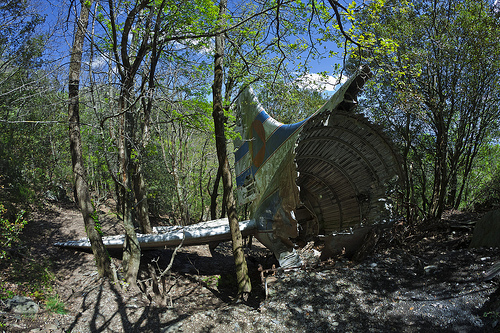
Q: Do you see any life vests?
A: No, there are no life vests.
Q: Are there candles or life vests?
A: No, there are no life vests or candles.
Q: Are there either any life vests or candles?
A: No, there are no life vests or candles.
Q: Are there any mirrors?
A: No, there are no mirrors.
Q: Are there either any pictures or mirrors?
A: No, there are no mirrors or pictures.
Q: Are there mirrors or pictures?
A: No, there are no mirrors or pictures.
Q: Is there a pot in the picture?
A: No, there are no pots.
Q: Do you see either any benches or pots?
A: No, there are no pots or benches.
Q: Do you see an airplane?
A: Yes, there is an airplane.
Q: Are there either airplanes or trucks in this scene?
A: Yes, there is an airplane.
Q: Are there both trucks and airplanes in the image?
A: No, there is an airplane but no trucks.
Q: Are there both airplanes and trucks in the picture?
A: No, there is an airplane but no trucks.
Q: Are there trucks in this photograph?
A: No, there are no trucks.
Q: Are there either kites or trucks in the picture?
A: No, there are no trucks or kites.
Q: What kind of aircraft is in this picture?
A: The aircraft is an airplane.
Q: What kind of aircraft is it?
A: The aircraft is an airplane.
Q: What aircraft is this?
A: This is an airplane.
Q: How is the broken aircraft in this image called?
A: The aircraft is an airplane.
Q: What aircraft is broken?
A: The aircraft is an airplane.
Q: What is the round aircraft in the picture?
A: The aircraft is an airplane.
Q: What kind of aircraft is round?
A: The aircraft is an airplane.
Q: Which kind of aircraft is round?
A: The aircraft is an airplane.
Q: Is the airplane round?
A: Yes, the airplane is round.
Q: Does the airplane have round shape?
A: Yes, the airplane is round.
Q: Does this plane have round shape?
A: Yes, the plane is round.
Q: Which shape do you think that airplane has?
A: The airplane has round shape.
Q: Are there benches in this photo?
A: No, there are no benches.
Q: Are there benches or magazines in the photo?
A: No, there are no benches or magazines.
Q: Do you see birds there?
A: No, there are no birds.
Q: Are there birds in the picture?
A: No, there are no birds.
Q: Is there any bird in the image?
A: No, there are no birds.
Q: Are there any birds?
A: No, there are no birds.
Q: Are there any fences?
A: No, there are no fences.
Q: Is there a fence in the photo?
A: No, there are no fences.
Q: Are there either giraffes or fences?
A: No, there are no fences or giraffes.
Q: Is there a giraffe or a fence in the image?
A: No, there are no fences or giraffes.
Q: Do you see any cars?
A: No, there are no cars.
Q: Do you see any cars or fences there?
A: No, there are no cars or fences.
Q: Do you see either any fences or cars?
A: No, there are no cars or fences.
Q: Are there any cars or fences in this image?
A: No, there are no cars or fences.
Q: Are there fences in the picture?
A: No, there are no fences.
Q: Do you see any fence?
A: No, there are no fences.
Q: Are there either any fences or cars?
A: No, there are no fences or cars.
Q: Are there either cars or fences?
A: No, there are no fences or cars.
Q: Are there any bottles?
A: No, there are no bottles.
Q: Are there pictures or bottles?
A: No, there are no bottles or pictures.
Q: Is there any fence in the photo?
A: No, there are no fences.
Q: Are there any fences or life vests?
A: No, there are no fences or life vests.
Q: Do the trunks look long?
A: Yes, the trunks are long.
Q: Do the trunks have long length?
A: Yes, the trunks are long.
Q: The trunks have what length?
A: The trunks are long.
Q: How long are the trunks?
A: The trunks are long.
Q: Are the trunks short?
A: No, the trunks are long.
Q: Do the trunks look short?
A: No, the trunks are long.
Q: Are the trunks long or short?
A: The trunks are long.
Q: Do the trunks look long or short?
A: The trunks are long.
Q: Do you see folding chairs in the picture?
A: No, there are no folding chairs.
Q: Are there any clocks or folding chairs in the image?
A: No, there are no folding chairs or clocks.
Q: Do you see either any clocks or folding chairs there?
A: No, there are no folding chairs or clocks.